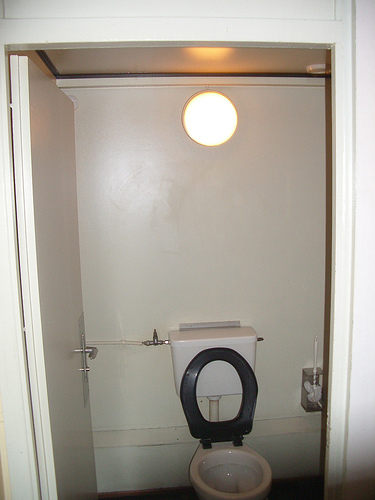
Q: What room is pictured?
A: It is a bathroom.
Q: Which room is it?
A: It is a bathroom.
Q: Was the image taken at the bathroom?
A: Yes, it was taken in the bathroom.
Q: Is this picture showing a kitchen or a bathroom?
A: It is showing a bathroom.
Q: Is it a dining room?
A: No, it is a bathroom.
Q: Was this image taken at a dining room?
A: No, the picture was taken in a bathroom.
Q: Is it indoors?
A: Yes, it is indoors.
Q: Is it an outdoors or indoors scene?
A: It is indoors.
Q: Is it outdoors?
A: No, it is indoors.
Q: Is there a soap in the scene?
A: No, there are no soaps.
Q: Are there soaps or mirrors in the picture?
A: No, there are no soaps or mirrors.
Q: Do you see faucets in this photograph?
A: No, there are no faucets.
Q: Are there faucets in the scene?
A: No, there are no faucets.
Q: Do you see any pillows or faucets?
A: No, there are no faucets or pillows.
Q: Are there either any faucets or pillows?
A: No, there are no faucets or pillows.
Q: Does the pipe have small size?
A: Yes, the pipe is small.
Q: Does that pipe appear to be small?
A: Yes, the pipe is small.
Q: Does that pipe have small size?
A: Yes, the pipe is small.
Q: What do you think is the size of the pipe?
A: The pipe is small.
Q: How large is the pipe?
A: The pipe is small.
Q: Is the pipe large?
A: No, the pipe is small.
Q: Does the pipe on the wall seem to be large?
A: No, the pipe is small.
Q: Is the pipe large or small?
A: The pipe is small.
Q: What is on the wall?
A: The pipe is on the wall.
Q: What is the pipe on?
A: The pipe is on the wall.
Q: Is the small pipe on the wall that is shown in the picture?
A: Yes, the pipe is on the wall.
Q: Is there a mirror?
A: No, there are no mirrors.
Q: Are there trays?
A: No, there are no trays.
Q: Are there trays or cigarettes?
A: No, there are no trays or cigarettes.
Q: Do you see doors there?
A: Yes, there is a door.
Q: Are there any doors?
A: Yes, there is a door.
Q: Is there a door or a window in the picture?
A: Yes, there is a door.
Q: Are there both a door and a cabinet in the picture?
A: No, there is a door but no cabinets.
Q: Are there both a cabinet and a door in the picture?
A: No, there is a door but no cabinets.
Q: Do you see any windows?
A: No, there are no windows.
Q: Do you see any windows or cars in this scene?
A: No, there are no windows or cars.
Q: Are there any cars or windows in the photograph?
A: No, there are no windows or cars.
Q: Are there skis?
A: No, there are no skis.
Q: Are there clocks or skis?
A: No, there are no skis or clocks.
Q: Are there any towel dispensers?
A: No, there are no towel dispensers.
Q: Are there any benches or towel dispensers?
A: No, there are no towel dispensers or benches.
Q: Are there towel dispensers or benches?
A: No, there are no towel dispensers or benches.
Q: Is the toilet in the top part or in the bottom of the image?
A: The toilet is in the bottom of the image.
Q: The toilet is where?
A: The toilet is in the bathroom.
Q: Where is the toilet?
A: The toilet is in the bathroom.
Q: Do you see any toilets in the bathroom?
A: Yes, there is a toilet in the bathroom.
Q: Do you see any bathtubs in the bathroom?
A: No, there is a toilet in the bathroom.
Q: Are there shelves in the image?
A: No, there are no shelves.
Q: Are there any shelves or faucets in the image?
A: No, there are no shelves or faucets.